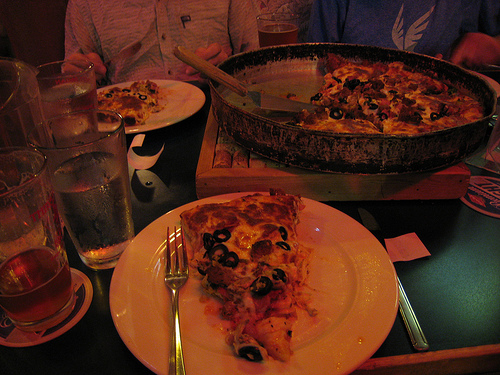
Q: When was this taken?
A: Mealtime.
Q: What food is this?
A: Pizza.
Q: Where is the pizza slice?
A: On a plate.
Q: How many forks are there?
A: One.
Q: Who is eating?
A: Two people.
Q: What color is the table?
A: Green.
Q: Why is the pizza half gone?
A: It has been eaten.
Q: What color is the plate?
A: White.